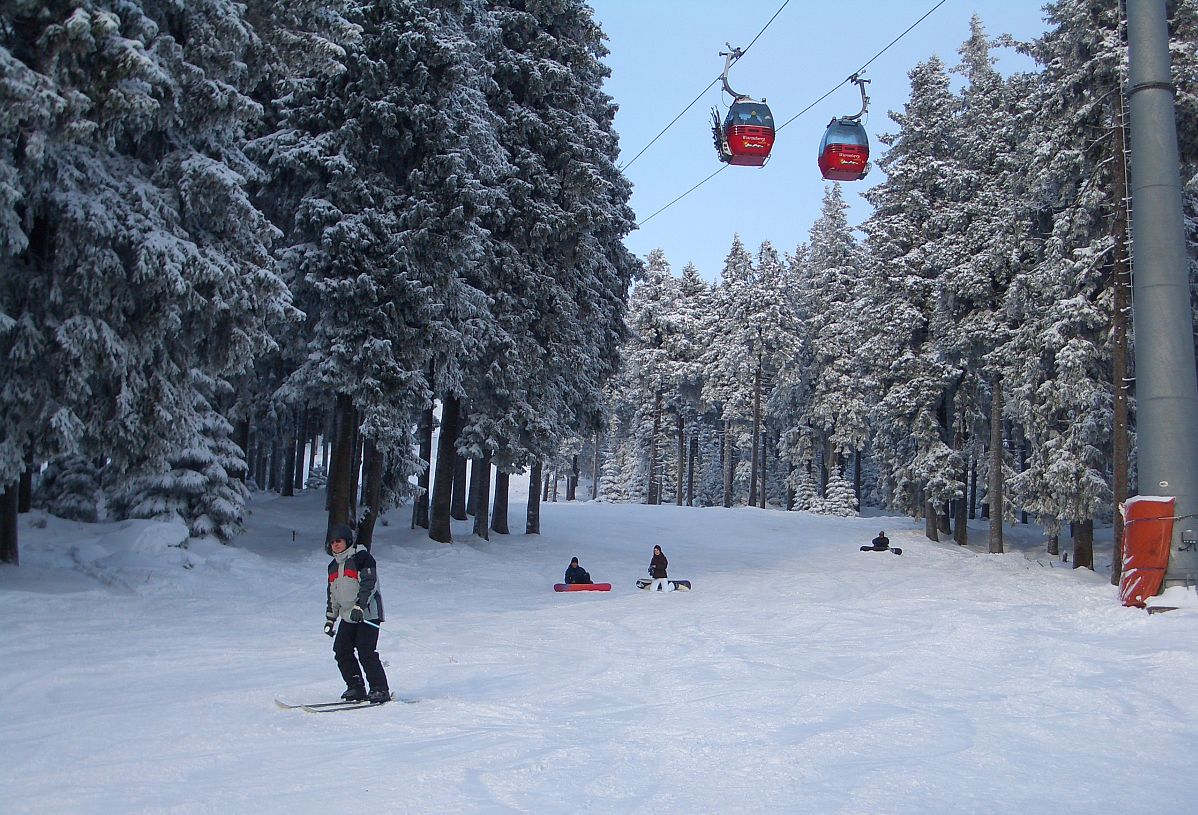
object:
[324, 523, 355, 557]
head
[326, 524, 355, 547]
hat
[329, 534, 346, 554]
face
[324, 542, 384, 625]
jacket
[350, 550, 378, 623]
left arm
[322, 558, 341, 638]
right arm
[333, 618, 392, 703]
pants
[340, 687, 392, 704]
shoes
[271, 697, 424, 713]
skis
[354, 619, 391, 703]
left leg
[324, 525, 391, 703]
man